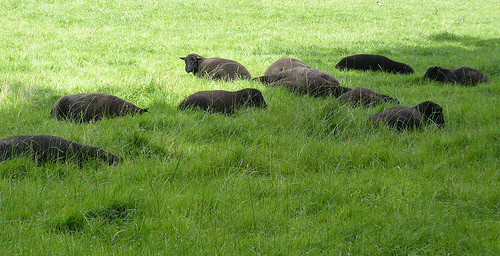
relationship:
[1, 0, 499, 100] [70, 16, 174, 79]
light hitting grass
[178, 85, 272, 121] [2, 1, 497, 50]
cow laying on grass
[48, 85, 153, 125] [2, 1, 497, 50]
cow laying on grass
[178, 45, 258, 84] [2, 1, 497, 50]
cow laying on grass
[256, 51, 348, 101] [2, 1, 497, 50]
cow laying on grass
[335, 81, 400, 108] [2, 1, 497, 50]
cow laying on grass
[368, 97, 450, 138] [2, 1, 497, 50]
cow laying on grass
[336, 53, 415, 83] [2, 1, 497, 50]
cow laying on grass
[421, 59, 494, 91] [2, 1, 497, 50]
cow laying on grass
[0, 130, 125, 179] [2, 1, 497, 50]
cow laying on grass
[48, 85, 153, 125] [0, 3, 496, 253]
cow laying on grass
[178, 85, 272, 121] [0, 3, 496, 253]
cow laying in grass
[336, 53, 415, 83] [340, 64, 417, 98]
cow laying on grass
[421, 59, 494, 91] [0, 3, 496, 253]
cow laying on grass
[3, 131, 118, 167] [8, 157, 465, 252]
animal laying in grass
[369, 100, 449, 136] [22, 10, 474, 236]
animal laying in grass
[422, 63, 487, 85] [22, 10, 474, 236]
animal laying in grass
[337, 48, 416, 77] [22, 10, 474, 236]
animal laying in grass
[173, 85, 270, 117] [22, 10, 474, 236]
animal laying in grass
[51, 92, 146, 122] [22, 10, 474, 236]
animal laying in grass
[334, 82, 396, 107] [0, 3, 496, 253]
animal laying in grass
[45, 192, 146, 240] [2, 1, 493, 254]
area in field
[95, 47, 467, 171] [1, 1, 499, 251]
animals laying on ground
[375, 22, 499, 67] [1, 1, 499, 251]
shadows on ground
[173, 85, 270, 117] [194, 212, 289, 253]
animal on grass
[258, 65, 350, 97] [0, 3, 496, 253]
animal on grass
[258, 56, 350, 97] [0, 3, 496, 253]
animal on grass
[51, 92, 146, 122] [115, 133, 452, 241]
animal on grass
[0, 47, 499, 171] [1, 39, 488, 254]
animals in shade'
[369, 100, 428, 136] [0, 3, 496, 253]
animal in grass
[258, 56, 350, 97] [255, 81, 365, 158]
animal in grass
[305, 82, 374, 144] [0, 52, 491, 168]
grass by animals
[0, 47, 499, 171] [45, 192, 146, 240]
animals in area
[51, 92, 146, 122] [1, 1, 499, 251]
animal on ground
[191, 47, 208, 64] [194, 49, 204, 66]
tag on ear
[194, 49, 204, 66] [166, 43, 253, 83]
ear on animal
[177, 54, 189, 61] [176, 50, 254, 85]
ear on sheep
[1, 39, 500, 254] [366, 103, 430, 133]
shade' on animal